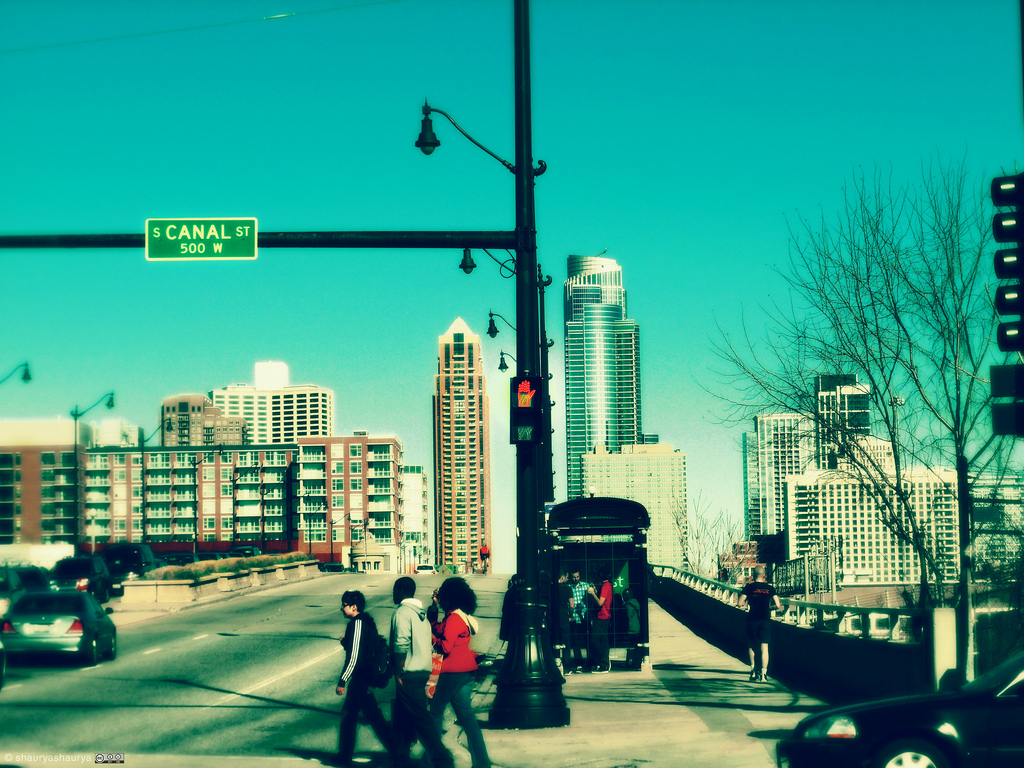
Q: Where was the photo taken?
A: On a city street.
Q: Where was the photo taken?
A: Near a cross walk.